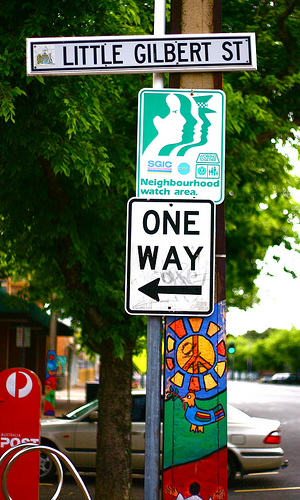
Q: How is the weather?
A: It is clear.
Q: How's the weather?
A: It is clear.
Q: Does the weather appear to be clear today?
A: Yes, it is clear.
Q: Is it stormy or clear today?
A: It is clear.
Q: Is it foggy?
A: No, it is clear.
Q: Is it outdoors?
A: Yes, it is outdoors.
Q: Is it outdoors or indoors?
A: It is outdoors.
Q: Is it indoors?
A: No, it is outdoors.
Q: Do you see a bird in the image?
A: Yes, there is a bird.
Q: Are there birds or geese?
A: Yes, there is a bird.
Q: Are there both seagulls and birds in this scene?
A: No, there is a bird but no seagulls.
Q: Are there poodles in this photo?
A: No, there are no poodles.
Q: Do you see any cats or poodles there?
A: No, there are no poodles or cats.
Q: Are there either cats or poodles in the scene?
A: No, there are no poodles or cats.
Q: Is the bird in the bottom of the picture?
A: Yes, the bird is in the bottom of the image.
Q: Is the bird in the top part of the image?
A: No, the bird is in the bottom of the image.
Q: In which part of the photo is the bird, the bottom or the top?
A: The bird is in the bottom of the image.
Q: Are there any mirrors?
A: No, there are no mirrors.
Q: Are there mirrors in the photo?
A: No, there are no mirrors.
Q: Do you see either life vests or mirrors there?
A: No, there are no mirrors or life vests.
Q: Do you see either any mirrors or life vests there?
A: No, there are no mirrors or life vests.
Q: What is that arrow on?
A: The arrow is on the sign.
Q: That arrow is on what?
A: The arrow is on the sign.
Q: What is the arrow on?
A: The arrow is on the sign.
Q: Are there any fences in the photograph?
A: No, there are no fences.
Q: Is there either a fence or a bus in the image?
A: No, there are no fences or buses.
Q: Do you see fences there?
A: No, there are no fences.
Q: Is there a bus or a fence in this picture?
A: No, there are no fences or buses.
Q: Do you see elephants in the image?
A: No, there are no elephants.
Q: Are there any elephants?
A: No, there are no elephants.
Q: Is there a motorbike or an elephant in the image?
A: No, there are no elephants or motorcycles.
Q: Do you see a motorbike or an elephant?
A: No, there are no elephants or motorcycles.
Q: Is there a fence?
A: No, there are no fences.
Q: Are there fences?
A: No, there are no fences.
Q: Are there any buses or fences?
A: No, there are no fences or buses.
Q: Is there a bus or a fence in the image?
A: No, there are no fences or buses.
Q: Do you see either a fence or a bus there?
A: No, there are no fences or buses.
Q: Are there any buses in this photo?
A: No, there are no buses.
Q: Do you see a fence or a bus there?
A: No, there are no buses or fences.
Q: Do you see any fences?
A: No, there are no fences.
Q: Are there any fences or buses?
A: No, there are no fences or buses.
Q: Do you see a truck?
A: No, there are no trucks.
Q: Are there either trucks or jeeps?
A: No, there are no trucks or jeeps.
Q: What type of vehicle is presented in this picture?
A: The vehicle is a car.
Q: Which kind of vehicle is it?
A: The vehicle is a car.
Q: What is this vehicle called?
A: This is a car.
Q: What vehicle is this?
A: This is a car.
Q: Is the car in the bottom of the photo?
A: Yes, the car is in the bottom of the image.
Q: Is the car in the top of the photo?
A: No, the car is in the bottom of the image.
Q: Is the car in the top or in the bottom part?
A: The car is in the bottom of the image.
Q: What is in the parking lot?
A: The car is in the parking lot.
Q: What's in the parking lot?
A: The car is in the parking lot.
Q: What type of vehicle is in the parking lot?
A: The vehicle is a car.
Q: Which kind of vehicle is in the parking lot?
A: The vehicle is a car.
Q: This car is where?
A: The car is in the parking lot.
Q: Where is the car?
A: The car is in the parking lot.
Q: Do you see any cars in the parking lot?
A: Yes, there is a car in the parking lot.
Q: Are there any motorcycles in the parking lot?
A: No, there is a car in the parking lot.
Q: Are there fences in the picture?
A: No, there are no fences.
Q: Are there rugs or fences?
A: No, there are no fences or rugs.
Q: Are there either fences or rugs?
A: No, there are no fences or rugs.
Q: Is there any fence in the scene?
A: No, there are no fences.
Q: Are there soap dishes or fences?
A: No, there are no fences or soap dishes.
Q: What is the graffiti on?
A: The graffiti is on the pole.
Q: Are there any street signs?
A: Yes, there is a street sign.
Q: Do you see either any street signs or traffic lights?
A: Yes, there is a street sign.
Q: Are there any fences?
A: No, there are no fences.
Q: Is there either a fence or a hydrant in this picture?
A: No, there are no fences or fire hydrants.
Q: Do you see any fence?
A: No, there are no fences.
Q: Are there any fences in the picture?
A: No, there are no fences.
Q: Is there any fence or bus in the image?
A: No, there are no fences or buses.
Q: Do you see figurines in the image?
A: No, there are no figurines.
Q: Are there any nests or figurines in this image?
A: No, there are no figurines or nests.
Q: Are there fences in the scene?
A: No, there are no fences.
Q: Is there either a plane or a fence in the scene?
A: No, there are no fences or airplanes.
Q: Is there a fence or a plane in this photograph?
A: No, there are no fences or airplanes.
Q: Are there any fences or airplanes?
A: No, there are no fences or airplanes.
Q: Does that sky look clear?
A: Yes, the sky is clear.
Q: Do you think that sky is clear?
A: Yes, the sky is clear.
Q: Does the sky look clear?
A: Yes, the sky is clear.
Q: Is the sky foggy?
A: No, the sky is clear.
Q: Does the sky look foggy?
A: No, the sky is clear.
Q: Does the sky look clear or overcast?
A: The sky is clear.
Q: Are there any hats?
A: Yes, there is a hat.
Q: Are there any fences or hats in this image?
A: Yes, there is a hat.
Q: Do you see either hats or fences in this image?
A: Yes, there is a hat.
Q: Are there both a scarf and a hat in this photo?
A: No, there is a hat but no scarves.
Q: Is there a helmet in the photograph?
A: No, there are no helmets.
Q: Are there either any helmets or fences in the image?
A: No, there are no helmets or fences.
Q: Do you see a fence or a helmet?
A: No, there are no helmets or fences.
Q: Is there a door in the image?
A: Yes, there is a door.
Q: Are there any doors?
A: Yes, there is a door.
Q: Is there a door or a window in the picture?
A: Yes, there is a door.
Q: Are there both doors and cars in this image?
A: Yes, there are both a door and a car.